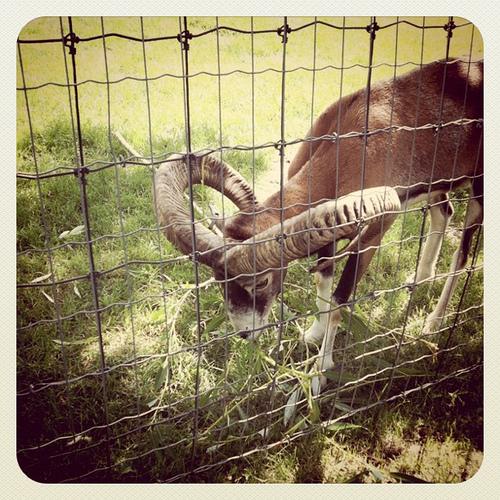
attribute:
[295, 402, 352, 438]
grass — poking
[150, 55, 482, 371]
goat — eating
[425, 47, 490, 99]
light — shining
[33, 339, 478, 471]
grass — covering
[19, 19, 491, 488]
grass — green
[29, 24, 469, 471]
wires — black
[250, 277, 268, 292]
eye — on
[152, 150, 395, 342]
head — bent down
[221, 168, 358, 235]
animal's neck — on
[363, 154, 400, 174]
fur — tan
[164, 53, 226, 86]
sun — on